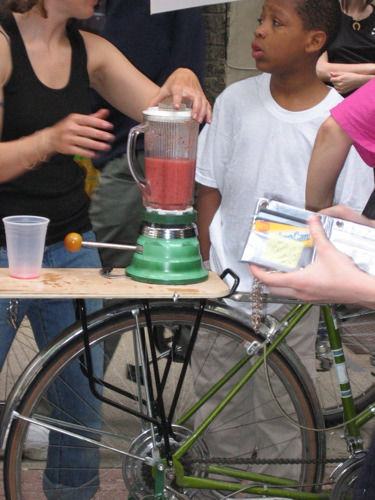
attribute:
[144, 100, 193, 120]
lid — white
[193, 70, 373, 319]
t-shirt — white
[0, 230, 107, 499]
jeans — blue, woman's, a pair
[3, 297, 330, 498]
tire — round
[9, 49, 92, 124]
tank top — black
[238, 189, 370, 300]
wallet — open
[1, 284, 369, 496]
bike frame — lime green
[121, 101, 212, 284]
blender — green, glass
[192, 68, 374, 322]
shirt — white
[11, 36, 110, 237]
shirt — black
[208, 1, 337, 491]
boy — young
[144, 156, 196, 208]
liquid — red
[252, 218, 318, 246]
card — plastic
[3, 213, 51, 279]
cup — plastic, empty